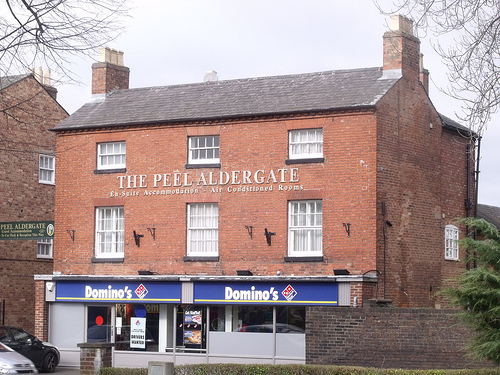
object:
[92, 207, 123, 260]
curtains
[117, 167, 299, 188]
letters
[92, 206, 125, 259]
windows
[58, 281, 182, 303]
sign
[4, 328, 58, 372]
car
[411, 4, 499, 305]
tree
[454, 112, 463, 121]
leaves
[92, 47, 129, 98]
chimney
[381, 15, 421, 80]
chimney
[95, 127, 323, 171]
three windows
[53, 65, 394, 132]
roof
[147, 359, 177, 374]
garbage can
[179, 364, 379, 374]
hedge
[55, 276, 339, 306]
domino's signs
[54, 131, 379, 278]
facade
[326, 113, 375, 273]
brick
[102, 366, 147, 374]
bush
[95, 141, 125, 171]
curtains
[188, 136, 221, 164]
curtains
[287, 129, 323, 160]
curtains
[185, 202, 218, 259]
curtains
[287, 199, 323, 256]
curtains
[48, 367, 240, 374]
sidewalk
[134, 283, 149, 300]
logo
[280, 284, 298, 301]
logo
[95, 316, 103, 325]
spot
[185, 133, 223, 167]
window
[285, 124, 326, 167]
window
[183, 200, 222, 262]
window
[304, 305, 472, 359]
wall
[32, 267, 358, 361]
store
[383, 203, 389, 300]
cord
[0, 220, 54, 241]
sign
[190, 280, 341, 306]
sign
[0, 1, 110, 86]
tree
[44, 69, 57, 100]
chimney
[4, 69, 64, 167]
building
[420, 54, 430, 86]
chimney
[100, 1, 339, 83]
clouds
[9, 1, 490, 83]
sky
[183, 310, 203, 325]
logo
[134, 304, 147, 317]
logo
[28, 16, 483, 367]
building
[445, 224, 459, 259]
curtains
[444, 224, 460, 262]
mullions